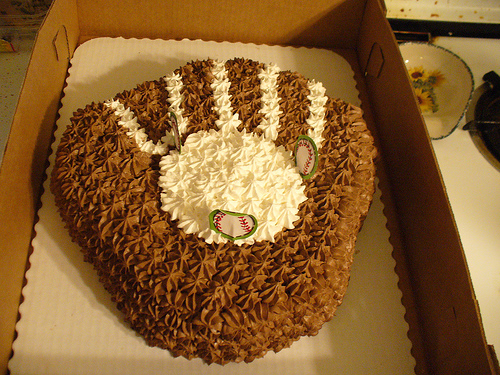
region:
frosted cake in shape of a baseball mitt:
[35, 32, 397, 368]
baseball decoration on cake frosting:
[203, 195, 261, 247]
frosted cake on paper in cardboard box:
[25, 66, 442, 373]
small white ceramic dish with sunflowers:
[381, 30, 479, 161]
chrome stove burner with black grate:
[461, 60, 499, 168]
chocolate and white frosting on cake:
[111, 157, 192, 235]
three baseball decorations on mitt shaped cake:
[150, 100, 328, 268]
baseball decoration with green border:
[279, 125, 326, 190]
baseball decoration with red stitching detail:
[288, 133, 329, 190]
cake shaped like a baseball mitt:
[28, 46, 386, 370]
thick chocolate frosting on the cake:
[146, 278, 273, 353]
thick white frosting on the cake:
[192, 140, 262, 185]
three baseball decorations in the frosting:
[154, 101, 326, 264]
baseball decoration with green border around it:
[288, 130, 325, 189]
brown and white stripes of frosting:
[193, 75, 293, 137]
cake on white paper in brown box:
[12, 77, 453, 372]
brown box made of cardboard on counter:
[404, 173, 496, 288]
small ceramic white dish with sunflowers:
[374, 36, 480, 144]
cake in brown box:
[444, 296, 472, 358]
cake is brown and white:
[81, 92, 343, 332]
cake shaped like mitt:
[68, 113, 357, 339]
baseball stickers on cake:
[207, 190, 247, 237]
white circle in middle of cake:
[165, 137, 299, 267]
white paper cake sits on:
[386, 336, 396, 348]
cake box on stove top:
[473, 228, 487, 253]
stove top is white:
[465, 186, 477, 212]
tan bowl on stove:
[441, 102, 448, 116]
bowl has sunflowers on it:
[438, 97, 457, 117]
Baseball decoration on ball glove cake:
[211, 208, 259, 245]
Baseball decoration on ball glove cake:
[290, 137, 322, 182]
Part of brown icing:
[200, 268, 252, 309]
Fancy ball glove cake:
[56, 56, 375, 368]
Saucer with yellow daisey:
[401, 38, 476, 141]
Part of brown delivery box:
[31, 64, 45, 130]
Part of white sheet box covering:
[33, 279, 69, 343]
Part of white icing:
[216, 168, 273, 198]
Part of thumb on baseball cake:
[53, 99, 142, 223]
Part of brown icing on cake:
[339, 150, 364, 206]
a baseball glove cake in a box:
[47, 50, 382, 360]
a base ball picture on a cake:
[290, 130, 320, 175]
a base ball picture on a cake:
[210, 205, 255, 240]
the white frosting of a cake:
[202, 146, 257, 189]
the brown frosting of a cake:
[165, 250, 256, 320]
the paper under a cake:
[75, 25, 138, 111]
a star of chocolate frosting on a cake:
[330, 161, 355, 191]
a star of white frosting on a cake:
[215, 111, 243, 131]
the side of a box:
[390, 177, 477, 327]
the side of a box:
[0, 75, 55, 215]